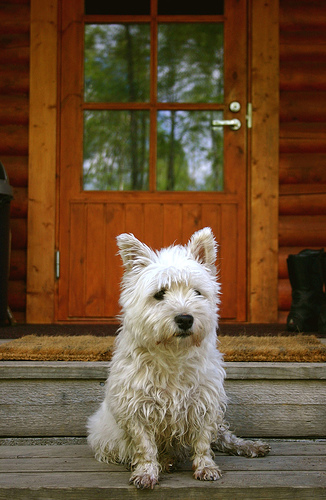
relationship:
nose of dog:
[172, 313, 194, 331] [74, 218, 280, 487]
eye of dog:
[152, 286, 166, 300] [74, 218, 280, 487]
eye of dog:
[191, 287, 201, 297] [74, 218, 280, 487]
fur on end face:
[155, 333, 204, 348] [121, 247, 221, 350]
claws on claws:
[129, 479, 154, 490] [129, 470, 230, 490]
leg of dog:
[210, 426, 272, 457] [74, 218, 280, 487]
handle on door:
[209, 117, 241, 130] [25, 3, 279, 325]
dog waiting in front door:
[74, 218, 280, 487] [25, 3, 279, 325]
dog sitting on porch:
[74, 218, 280, 487] [4, 324, 315, 495]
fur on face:
[121, 361, 182, 410] [109, 224, 229, 349]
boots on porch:
[281, 250, 315, 333] [2, 325, 315, 438]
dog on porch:
[74, 218, 280, 487] [2, 325, 315, 438]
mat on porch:
[6, 329, 315, 359] [2, 325, 315, 438]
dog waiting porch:
[74, 218, 280, 487] [4, 324, 315, 495]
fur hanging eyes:
[143, 367, 196, 401] [150, 288, 167, 301]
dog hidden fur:
[74, 218, 280, 487] [147, 360, 200, 413]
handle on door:
[209, 117, 241, 130] [41, 9, 282, 330]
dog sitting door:
[74, 218, 280, 487] [41, 9, 282, 330]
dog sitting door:
[74, 218, 280, 487] [48, 13, 268, 343]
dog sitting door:
[74, 218, 280, 487] [48, 0, 254, 317]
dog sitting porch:
[74, 218, 280, 487] [4, 324, 315, 495]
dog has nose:
[74, 218, 280, 487] [173, 310, 199, 339]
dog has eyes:
[74, 218, 280, 487] [150, 283, 206, 302]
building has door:
[5, 10, 325, 324] [48, 13, 268, 343]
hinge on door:
[50, 245, 64, 284] [48, 0, 254, 317]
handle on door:
[209, 117, 241, 130] [48, 0, 254, 317]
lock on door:
[211, 100, 245, 132] [48, 0, 254, 317]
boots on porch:
[281, 250, 323, 335] [4, 324, 315, 495]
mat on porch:
[6, 329, 315, 359] [4, 324, 315, 495]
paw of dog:
[125, 472, 160, 492] [98, 229, 239, 482]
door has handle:
[48, 0, 254, 317] [204, 117, 244, 131]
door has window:
[48, 0, 254, 317] [158, 108, 224, 190]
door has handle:
[48, 0, 254, 317] [208, 118, 243, 129]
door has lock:
[48, 0, 254, 317] [227, 98, 242, 112]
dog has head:
[74, 218, 280, 487] [108, 221, 226, 351]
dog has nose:
[74, 218, 280, 487] [171, 310, 195, 328]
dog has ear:
[74, 218, 280, 487] [112, 226, 154, 262]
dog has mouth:
[74, 218, 280, 487] [171, 326, 195, 340]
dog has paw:
[74, 218, 280, 487] [126, 464, 161, 491]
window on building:
[158, 108, 224, 190] [5, 10, 325, 324]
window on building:
[81, 22, 151, 105] [5, 10, 325, 324]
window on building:
[154, 1, 226, 18] [2, 54, 325, 361]